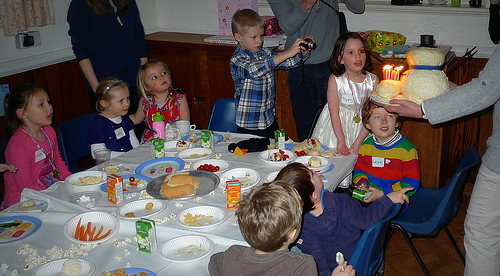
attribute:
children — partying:
[63, 47, 359, 181]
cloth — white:
[38, 206, 73, 228]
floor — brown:
[412, 234, 465, 271]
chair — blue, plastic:
[429, 163, 479, 239]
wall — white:
[153, 9, 224, 36]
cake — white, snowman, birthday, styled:
[411, 47, 459, 110]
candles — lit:
[351, 55, 414, 97]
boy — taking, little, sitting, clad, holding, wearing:
[239, 21, 332, 137]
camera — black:
[293, 37, 316, 58]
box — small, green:
[127, 219, 151, 232]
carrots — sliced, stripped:
[69, 213, 112, 241]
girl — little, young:
[20, 82, 66, 177]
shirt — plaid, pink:
[225, 48, 297, 143]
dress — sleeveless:
[315, 65, 364, 129]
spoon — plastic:
[325, 251, 356, 269]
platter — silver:
[367, 91, 407, 115]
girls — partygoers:
[85, 56, 216, 131]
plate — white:
[161, 206, 230, 231]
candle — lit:
[373, 61, 384, 79]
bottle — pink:
[145, 108, 184, 165]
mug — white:
[174, 113, 201, 129]